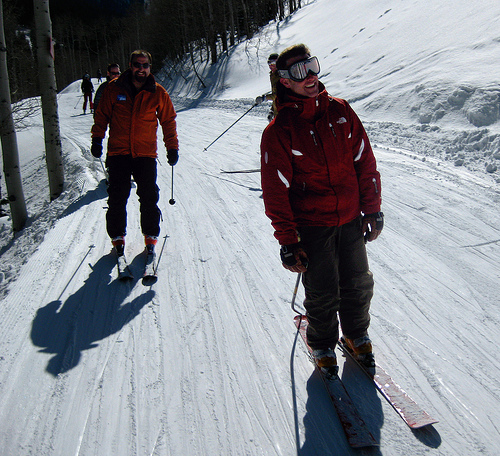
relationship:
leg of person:
[339, 241, 374, 340] [254, 45, 420, 351]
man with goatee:
[92, 49, 177, 261] [131, 74, 148, 83]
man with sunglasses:
[92, 49, 177, 261] [129, 59, 152, 69]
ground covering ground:
[0, 0, 500, 456] [27, 40, 484, 420]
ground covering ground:
[0, 0, 500, 456] [8, 72, 495, 454]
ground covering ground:
[0, 0, 500, 456] [143, 223, 247, 364]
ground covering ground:
[0, 0, 500, 456] [43, 60, 484, 445]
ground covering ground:
[0, 0, 500, 456] [32, 49, 469, 436]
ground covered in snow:
[8, 72, 495, 454] [8, 279, 248, 441]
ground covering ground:
[0, 0, 500, 456] [0, 0, 498, 454]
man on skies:
[259, 45, 384, 373] [291, 314, 438, 447]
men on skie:
[82, 48, 385, 373] [258, 249, 348, 390]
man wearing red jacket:
[259, 42, 384, 373] [267, 100, 384, 245]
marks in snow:
[157, 321, 353, 450] [16, 86, 498, 453]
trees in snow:
[1, 0, 308, 103] [338, 4, 483, 90]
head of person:
[276, 44, 320, 98] [267, 46, 387, 391]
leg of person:
[302, 227, 337, 349] [260, 43, 384, 365]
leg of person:
[340, 218, 372, 335] [260, 43, 384, 365]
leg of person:
[299, 239, 340, 349] [209, 26, 445, 387]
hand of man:
[89, 146, 101, 157] [91, 49, 180, 255]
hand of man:
[351, 198, 411, 258] [259, 42, 384, 373]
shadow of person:
[292, 359, 392, 451] [237, 43, 446, 434]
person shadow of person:
[30, 248, 157, 378] [67, 43, 211, 311]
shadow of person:
[173, 46, 236, 111] [74, 71, 94, 121]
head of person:
[124, 51, 154, 82] [88, 49, 179, 291]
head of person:
[266, 44, 321, 95] [253, 43, 387, 383]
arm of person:
[261, 137, 298, 244] [264, 44, 359, 228]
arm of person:
[350, 117, 380, 212] [260, 43, 384, 365]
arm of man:
[261, 137, 298, 244] [91, 49, 180, 255]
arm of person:
[157, 101, 179, 147] [80, 72, 95, 114]